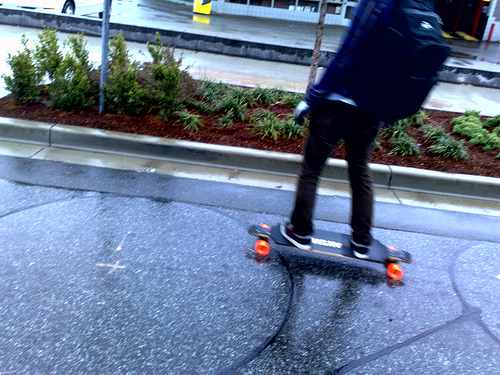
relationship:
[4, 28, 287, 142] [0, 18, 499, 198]
plants in median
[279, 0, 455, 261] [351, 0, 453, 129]
man carrying backpack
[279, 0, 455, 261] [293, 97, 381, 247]
man wearing jeans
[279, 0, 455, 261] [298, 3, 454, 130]
man wearing backpack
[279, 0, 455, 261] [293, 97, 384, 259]
man wearing jeans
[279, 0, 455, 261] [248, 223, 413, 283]
man on board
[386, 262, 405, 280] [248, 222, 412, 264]
wheel on board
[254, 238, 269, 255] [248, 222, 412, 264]
wheel on board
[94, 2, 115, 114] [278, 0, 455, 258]
pole near boy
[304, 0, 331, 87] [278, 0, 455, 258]
pole near boy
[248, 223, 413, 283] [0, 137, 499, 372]
board on ground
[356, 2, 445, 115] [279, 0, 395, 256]
backpack on man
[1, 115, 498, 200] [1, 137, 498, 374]
curb near road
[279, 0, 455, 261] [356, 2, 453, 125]
man wears backpack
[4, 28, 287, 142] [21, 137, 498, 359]
plants near road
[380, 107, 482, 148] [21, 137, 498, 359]
plants near road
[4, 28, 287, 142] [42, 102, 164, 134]
plants in dirt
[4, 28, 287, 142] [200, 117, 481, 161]
plants in dirt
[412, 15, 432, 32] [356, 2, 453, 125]
logo on a book backpack